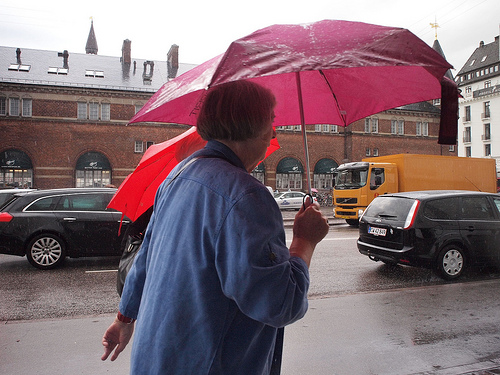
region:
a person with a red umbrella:
[156, 21, 448, 371]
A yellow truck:
[333, 156, 494, 201]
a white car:
[273, 190, 315, 217]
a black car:
[368, 195, 498, 292]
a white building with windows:
[458, 38, 498, 174]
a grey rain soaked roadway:
[327, 265, 488, 365]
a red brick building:
[3, 47, 153, 180]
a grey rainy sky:
[7, 1, 492, 51]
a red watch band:
[113, 307, 136, 324]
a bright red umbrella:
[105, 133, 165, 231]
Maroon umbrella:
[148, 32, 475, 122]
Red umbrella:
[115, 148, 187, 215]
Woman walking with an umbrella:
[90, 94, 317, 370]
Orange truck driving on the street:
[339, 147, 498, 212]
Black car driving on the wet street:
[370, 183, 498, 278]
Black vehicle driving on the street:
[9, 189, 125, 269]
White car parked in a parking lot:
[271, 187, 323, 211]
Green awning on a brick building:
[66, 142, 128, 179]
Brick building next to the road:
[18, 116, 138, 186]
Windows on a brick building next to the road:
[67, 95, 107, 125]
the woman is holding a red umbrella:
[88, 7, 477, 374]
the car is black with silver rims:
[1, 179, 156, 284]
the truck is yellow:
[322, 132, 497, 239]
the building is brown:
[0, 31, 459, 206]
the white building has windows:
[447, 34, 499, 184]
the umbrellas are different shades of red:
[83, 7, 460, 257]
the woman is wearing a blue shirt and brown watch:
[92, 71, 330, 373]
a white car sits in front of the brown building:
[221, 97, 397, 239]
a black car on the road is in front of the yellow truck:
[308, 130, 498, 293]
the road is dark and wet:
[0, 177, 499, 372]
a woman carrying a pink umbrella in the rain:
[75, 12, 454, 374]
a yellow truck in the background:
[331, 144, 497, 244]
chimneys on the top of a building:
[10, 43, 186, 83]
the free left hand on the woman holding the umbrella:
[80, 314, 156, 363]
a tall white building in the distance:
[453, 28, 498, 177]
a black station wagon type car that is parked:
[347, 189, 498, 274]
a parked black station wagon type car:
[4, 186, 142, 268]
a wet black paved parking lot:
[329, 282, 489, 370]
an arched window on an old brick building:
[72, 148, 111, 193]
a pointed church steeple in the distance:
[77, 14, 104, 56]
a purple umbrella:
[138, 17, 459, 229]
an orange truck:
[331, 151, 499, 223]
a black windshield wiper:
[373, 209, 399, 221]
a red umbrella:
[107, 113, 283, 220]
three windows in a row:
[73, 99, 116, 121]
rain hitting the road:
[3, 259, 499, 374]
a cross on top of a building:
[428, 16, 448, 63]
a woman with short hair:
[188, 75, 285, 171]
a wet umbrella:
[130, 12, 468, 155]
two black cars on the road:
[3, 176, 497, 291]